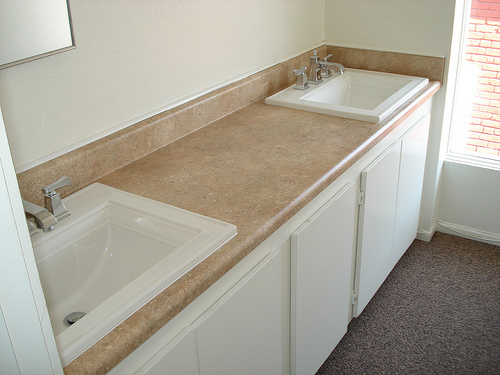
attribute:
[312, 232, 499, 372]
carpet — plush, nice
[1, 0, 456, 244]
wall — painted off white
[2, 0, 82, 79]
mirror — vanity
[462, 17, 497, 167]
wall — brick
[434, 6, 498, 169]
window — bathroom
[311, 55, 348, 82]
faucet — chrome, bathroom, sink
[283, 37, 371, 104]
faucet handle — chrome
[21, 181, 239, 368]
bathroom sink — white, porcelain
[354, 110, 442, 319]
cabinet — white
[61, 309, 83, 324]
drain — chrome, sink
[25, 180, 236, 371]
sink — white, square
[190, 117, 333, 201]
counter — brownish color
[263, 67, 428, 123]
sink — white, porcelain, bathroom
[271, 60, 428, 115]
sink — white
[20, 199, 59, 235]
faucet — sink, bathroom, chrome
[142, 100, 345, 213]
counter — top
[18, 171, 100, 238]
faucet — chrome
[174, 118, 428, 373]
cabinets — white